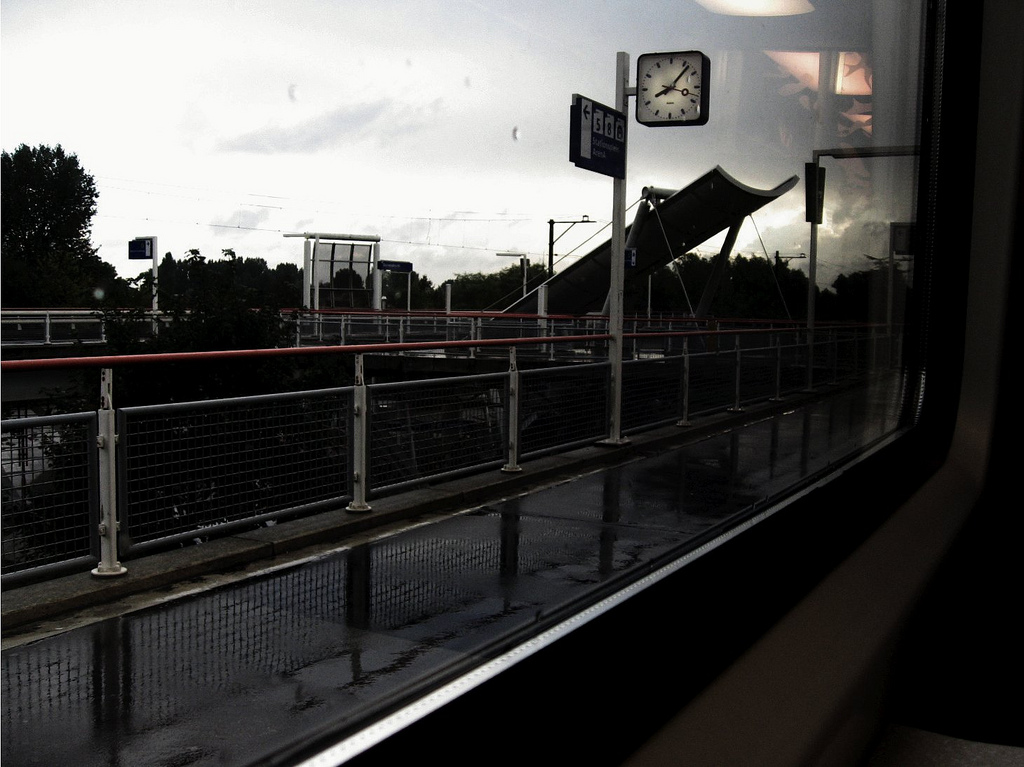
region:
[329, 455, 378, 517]
pole on the ground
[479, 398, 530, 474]
pole on the ground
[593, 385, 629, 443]
pole on the ground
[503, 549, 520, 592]
pole on the ground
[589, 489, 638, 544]
pole on the ground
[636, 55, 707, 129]
black and white clock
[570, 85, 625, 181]
black and white sign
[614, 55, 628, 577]
the pole is metal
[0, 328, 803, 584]
the fence is metal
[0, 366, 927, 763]
the fence is small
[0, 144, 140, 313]
the tree is dark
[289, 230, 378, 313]
the thing is white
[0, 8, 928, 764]
window of a vehicle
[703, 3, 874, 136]
reflections on the window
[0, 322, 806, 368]
top of railing is red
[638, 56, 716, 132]
a clock on a pole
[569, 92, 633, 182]
a black and white sing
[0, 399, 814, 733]
a reflection of the fence in the water on the ground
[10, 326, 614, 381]
the red top railing of the fence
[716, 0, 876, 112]
reflection of lights in the window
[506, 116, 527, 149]
a drop of water on the window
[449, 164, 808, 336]
a ramp going up in the air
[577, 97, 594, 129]
a black arrow on the sign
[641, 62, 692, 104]
black hands on the clock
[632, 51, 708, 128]
clock on the pole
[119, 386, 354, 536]
Metal rail on the fence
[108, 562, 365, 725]
Metal rail on the fence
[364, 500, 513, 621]
Metal rail on the fence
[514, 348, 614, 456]
Metal rail on the fence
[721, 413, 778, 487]
Metal rail on the fence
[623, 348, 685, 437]
Metal rail on the fence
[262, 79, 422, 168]
clouds in the sky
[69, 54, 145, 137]
the sky is grey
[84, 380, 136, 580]
a white pole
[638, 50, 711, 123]
a clock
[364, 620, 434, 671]
water on the ground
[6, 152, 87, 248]
the bush is green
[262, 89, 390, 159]
the clouds in the sky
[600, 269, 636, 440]
a pole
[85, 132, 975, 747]
a scene during the day time time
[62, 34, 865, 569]
a scene of a train station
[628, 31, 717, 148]
a white clock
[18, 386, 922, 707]
a gray fence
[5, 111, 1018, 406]
some trees in the background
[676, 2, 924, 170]
reflection of lights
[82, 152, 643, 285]
some power lines in the air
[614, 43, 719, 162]
black and white clock